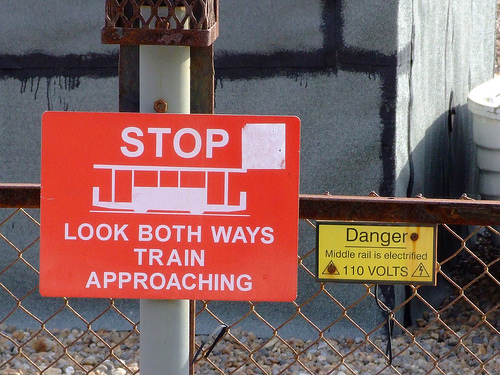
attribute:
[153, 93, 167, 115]
bolt — rusty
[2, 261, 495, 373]
gravel — covering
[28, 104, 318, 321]
sign — stop sign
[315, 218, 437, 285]
sign — rusty, black, yellow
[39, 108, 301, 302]
stop sign — bright, orange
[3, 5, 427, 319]
sealer — black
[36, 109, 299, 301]
warning sign — red, white, train warning sign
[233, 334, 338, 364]
pebbles — strewn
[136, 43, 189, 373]
pole — gray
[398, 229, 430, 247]
bolt — rusted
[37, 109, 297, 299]
sign — red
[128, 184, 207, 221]
train — picture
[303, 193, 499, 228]
rail — metal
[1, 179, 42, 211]
rail — metal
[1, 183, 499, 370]
fence — electric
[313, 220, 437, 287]
yellow sign — danger sign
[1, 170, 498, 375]
cage — rusted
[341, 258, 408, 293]
marking — black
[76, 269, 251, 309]
writing — white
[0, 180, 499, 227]
rail — electrified 